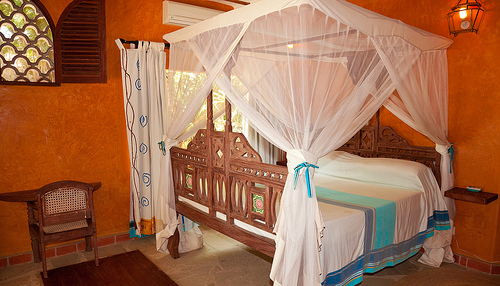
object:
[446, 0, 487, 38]
light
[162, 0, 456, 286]
drapes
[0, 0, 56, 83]
glass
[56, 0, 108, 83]
cover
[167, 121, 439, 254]
bed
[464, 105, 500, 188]
wall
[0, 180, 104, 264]
cair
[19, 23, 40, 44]
circular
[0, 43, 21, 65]
circular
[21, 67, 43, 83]
circular